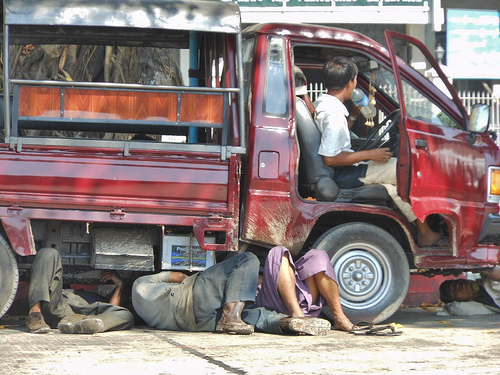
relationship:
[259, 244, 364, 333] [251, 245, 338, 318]
man wearing pants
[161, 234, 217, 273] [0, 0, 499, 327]
battery under truck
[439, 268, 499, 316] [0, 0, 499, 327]
man under truck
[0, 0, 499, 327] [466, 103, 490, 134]
truck has a mirror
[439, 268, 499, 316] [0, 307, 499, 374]
man laying on ground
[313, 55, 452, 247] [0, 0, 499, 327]
man sitting in truck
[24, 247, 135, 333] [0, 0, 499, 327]
man are under truck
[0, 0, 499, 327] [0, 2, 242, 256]
truck has a truck bed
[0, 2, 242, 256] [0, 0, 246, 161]
truck bed has a canopy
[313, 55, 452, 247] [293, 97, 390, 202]
man in drivers seat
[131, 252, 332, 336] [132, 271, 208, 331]
man wearing a shirt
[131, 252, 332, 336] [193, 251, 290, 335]
man wearing jeans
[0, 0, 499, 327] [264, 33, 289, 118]
truck has a small window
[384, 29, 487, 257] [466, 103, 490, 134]
door has a mirror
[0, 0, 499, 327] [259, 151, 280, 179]
truck has a gas door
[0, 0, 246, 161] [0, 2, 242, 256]
canopy over truck bed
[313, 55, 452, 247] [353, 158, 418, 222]
man has pants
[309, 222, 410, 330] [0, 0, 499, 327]
wheel part of truck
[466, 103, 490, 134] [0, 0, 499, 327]
mirror on truck